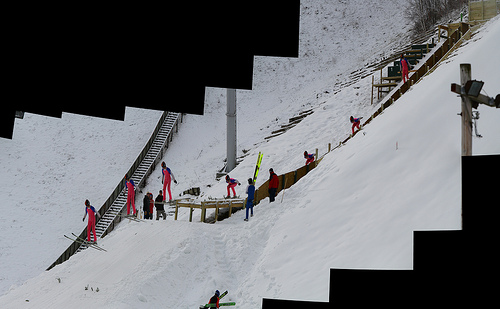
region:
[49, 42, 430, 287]
skiers wearing the same pink and blue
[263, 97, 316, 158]
steps up the slope in snow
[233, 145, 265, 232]
man in blue standing near yellow sign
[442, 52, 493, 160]
lights mounted to a post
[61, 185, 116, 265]
skier jumping in pink and blue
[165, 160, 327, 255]
wooden ramp for jumping on skis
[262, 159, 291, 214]
man in red jacket and dark pants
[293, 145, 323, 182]
skier squatting before jump on ramp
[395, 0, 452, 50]
dead bushes sticking out of the snow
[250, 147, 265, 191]
yellow and black flag sticking up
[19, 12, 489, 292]
Ski slope and ski jumper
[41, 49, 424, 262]
Time lapsed photo of ski jumper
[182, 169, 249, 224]
Ski jumper and wooden platform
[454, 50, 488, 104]
Light attached to pole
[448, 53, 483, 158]
Brown wooden support pole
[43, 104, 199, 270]
Brown wooden staircase on ski slope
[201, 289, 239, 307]
Person carrying pair of skis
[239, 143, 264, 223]
Man carrying yellow flag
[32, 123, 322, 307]
Snow covered ski slope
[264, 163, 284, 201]
Individual in red and black winter outfit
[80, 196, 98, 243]
Person sking in the air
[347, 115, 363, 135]
Skier coming down the snow covered mountain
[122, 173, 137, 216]
Person in a red and black ski outfit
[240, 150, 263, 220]
Skier holding his skis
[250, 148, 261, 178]
Yellow skis held by skier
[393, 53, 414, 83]
Red and black ski outfit worn by skier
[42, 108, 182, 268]
Tracks to take you to the top of mountain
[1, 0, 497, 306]
Snow covered mountain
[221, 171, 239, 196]
Skier getting ready to lift off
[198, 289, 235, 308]
Skier carrying his skis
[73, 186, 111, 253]
Person in a ski suite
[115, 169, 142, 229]
Person in a ski suite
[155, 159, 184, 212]
Person in a ski suite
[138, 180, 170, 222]
Person in a ski suite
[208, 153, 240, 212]
Person in a ski suite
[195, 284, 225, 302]
Person in a ski suite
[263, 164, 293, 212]
Person in a ski suite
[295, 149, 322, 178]
Person in a ski suite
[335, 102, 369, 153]
Person in a ski suite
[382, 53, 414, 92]
Person in a ski suite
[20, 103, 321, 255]
a skier jumping off lift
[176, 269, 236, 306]
a skier walking up the hill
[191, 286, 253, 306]
green ski under arm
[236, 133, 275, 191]
a pole with green banner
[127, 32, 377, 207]
stairs leading to top of hill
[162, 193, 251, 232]
platform to jump off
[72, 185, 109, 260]
a skier in red and black suit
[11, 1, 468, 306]
snow covers the ground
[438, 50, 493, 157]
a wooden pole with black object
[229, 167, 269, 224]
a person standing in all blue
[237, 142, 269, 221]
person in blue carrying skis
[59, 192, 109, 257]
person in pink jumping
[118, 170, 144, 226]
person in pink jumping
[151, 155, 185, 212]
person in pink jumping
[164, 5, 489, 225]
a ski jump ramp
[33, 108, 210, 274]
a long flight of stairs